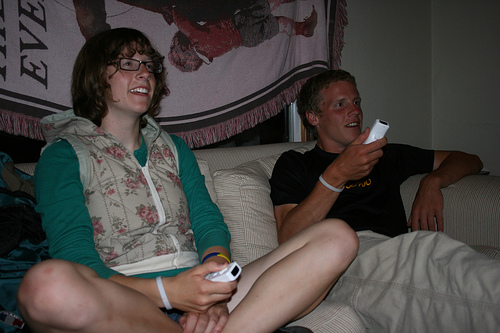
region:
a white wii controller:
[360, 115, 391, 145]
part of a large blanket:
[0, 0, 355, 146]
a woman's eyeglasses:
[95, 50, 165, 75]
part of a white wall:
[430, 0, 495, 170]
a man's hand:
[405, 170, 445, 240]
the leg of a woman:
[187, 220, 364, 330]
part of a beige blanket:
[295, 211, 490, 326]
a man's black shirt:
[272, 121, 437, 243]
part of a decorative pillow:
[1, 154, 45, 330]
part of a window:
[231, 105, 296, 150]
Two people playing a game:
[15, 23, 483, 331]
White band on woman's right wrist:
[152, 272, 173, 308]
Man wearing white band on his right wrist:
[313, 169, 342, 197]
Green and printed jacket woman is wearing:
[34, 118, 229, 276]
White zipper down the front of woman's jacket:
[137, 160, 166, 222]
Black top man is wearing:
[271, 141, 428, 233]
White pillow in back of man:
[205, 145, 310, 265]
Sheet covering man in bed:
[321, 222, 494, 327]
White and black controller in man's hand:
[363, 117, 389, 147]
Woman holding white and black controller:
[201, 259, 241, 284]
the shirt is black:
[283, 128, 389, 250]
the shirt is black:
[275, 133, 455, 271]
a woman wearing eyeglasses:
[73, 21, 207, 141]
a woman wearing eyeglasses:
[94, 45, 182, 125]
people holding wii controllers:
[34, 16, 481, 314]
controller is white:
[196, 261, 266, 300]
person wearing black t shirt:
[265, 110, 432, 230]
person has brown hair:
[49, 12, 184, 115]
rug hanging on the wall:
[1, 1, 363, 174]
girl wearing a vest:
[35, 103, 220, 268]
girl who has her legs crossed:
[23, 35, 395, 331]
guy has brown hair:
[289, 55, 358, 130]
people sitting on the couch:
[28, 44, 487, 327]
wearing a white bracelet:
[118, 262, 187, 319]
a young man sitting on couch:
[272, 64, 499, 331]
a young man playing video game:
[268, 65, 498, 332]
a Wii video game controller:
[363, 117, 392, 146]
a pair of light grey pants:
[334, 230, 499, 330]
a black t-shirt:
[271, 143, 434, 235]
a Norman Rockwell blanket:
[1, 0, 342, 145]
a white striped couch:
[197, 149, 497, 330]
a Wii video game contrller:
[203, 262, 241, 285]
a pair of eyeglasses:
[104, 58, 161, 74]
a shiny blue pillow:
[0, 190, 47, 327]